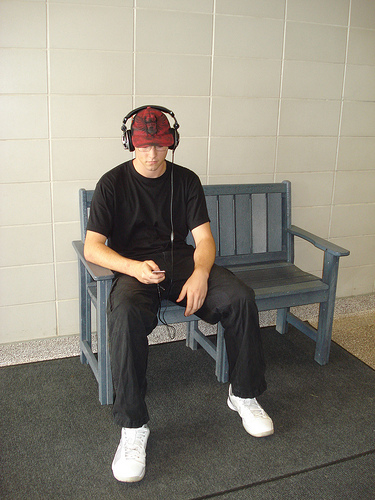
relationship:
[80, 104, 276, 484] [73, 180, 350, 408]
man on bench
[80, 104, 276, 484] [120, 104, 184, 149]
man wearing headphones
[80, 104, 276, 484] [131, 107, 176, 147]
man wearing hat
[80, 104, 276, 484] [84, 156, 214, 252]
man wearing shirt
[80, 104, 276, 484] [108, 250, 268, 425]
man wearing pants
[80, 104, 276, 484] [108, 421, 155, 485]
man wearing shoe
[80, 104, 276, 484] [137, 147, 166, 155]
man wearing glasses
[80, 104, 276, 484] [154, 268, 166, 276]
man holding ipod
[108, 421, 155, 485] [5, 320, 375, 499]
shoe on rug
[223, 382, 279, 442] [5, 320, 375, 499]
shoe on rug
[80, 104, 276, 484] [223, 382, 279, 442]
man wearing shoe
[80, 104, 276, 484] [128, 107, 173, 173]
man has head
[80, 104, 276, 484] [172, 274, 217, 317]
man has hand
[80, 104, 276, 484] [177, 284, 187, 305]
man has thumb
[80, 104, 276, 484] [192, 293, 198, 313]
man has finger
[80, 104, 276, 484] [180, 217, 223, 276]
man has arm